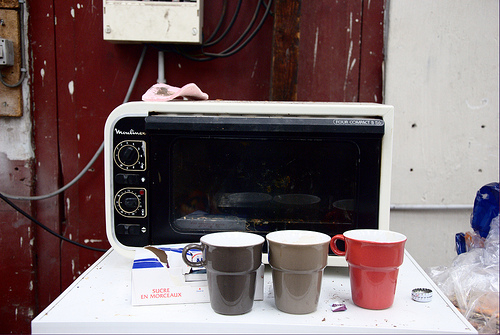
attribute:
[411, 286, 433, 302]
cap — lying on table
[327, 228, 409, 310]
cups — different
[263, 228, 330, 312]
cups — different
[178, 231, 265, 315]
cups — different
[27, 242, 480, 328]
table — white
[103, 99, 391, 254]
microwave — black, white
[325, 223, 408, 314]
mug — red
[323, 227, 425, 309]
mug — red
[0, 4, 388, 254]
wall — wooden, red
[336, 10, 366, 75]
paint — chipped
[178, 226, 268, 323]
mug — dark brown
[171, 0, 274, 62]
cords — black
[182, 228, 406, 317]
cups — different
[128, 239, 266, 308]
box — white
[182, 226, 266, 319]
mug — brown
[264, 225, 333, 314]
mug — brown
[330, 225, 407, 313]
mug — red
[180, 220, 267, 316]
cup — coffee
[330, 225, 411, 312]
cup — different, coffee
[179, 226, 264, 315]
cup — different, coffee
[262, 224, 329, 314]
cup — different, coffee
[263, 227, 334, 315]
cup — different